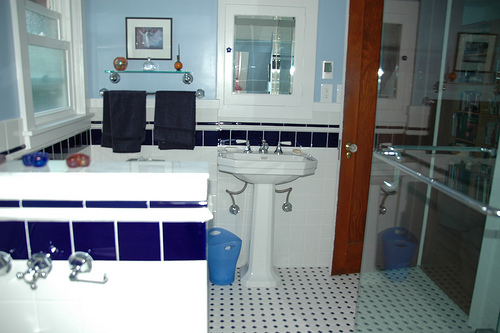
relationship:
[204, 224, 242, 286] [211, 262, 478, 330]
trash can on bathroom floor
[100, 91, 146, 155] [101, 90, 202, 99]
towel on rack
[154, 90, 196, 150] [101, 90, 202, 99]
black towel on rack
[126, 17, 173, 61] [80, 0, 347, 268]
art on bathroom wall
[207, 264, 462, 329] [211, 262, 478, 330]
tile on bathroom floor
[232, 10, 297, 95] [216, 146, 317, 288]
cabinet mirror above bathroom sink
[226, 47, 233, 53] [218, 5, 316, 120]
handle on cabinet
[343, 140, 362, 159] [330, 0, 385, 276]
door handle on door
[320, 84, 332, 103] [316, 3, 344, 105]
plug on bathroom wall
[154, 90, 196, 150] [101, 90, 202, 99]
black towel hanging from rack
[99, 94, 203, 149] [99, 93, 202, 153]
rack for towels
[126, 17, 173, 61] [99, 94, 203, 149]
art over rack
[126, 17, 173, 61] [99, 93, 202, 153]
art over towels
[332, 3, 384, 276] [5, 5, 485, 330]
door to bathroom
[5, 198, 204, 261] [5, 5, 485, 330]
tile in bathroom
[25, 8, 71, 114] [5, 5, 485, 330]
framed window in bathroom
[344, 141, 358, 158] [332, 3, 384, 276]
door handle on door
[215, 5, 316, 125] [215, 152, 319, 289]
cabinet above bathroom sink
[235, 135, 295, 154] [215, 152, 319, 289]
faucet on bathroom sink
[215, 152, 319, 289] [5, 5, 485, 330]
bathroom sink in bathroom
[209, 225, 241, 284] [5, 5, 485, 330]
basket in bathroom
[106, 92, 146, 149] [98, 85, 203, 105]
towel on rack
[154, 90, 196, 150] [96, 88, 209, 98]
black towel on rack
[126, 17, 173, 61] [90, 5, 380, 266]
art on wall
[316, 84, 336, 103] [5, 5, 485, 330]
plug in bathroom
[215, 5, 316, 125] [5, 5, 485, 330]
cabinet in bathroom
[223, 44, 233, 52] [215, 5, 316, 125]
handle on cabinet